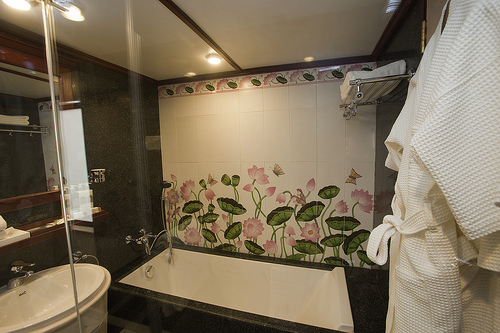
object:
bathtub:
[106, 241, 382, 333]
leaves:
[220, 218, 248, 242]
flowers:
[165, 168, 243, 213]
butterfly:
[266, 159, 289, 180]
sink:
[0, 261, 113, 332]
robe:
[370, 1, 500, 331]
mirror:
[0, 57, 65, 204]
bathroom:
[3, 1, 498, 330]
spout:
[127, 224, 169, 261]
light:
[201, 50, 223, 66]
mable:
[225, 270, 318, 309]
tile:
[162, 58, 376, 269]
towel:
[330, 58, 409, 99]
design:
[157, 156, 412, 271]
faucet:
[120, 225, 159, 259]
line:
[166, 4, 244, 68]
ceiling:
[0, 1, 406, 81]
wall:
[162, 55, 404, 329]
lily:
[281, 221, 337, 247]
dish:
[1, 224, 32, 245]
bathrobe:
[364, 1, 500, 332]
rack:
[338, 67, 418, 120]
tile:
[141, 302, 199, 326]